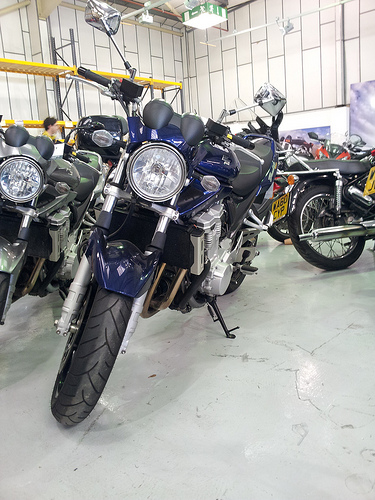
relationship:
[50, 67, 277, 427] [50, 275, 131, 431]
motorcycle has a tire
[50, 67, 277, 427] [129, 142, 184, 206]
motorcycle has a headlight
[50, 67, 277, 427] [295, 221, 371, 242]
motorcycle has a muffler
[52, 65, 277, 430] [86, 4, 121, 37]
bike has a mirror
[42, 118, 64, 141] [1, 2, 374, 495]
man in shop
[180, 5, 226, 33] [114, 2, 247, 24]
light on ceiling